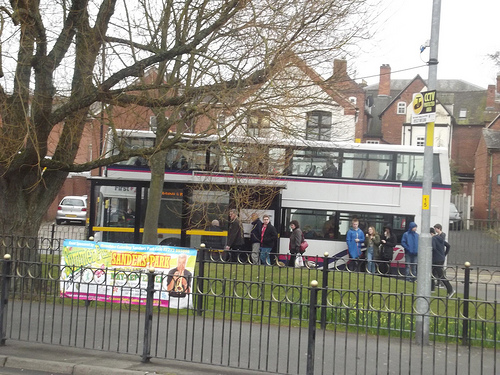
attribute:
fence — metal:
[5, 248, 495, 372]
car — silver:
[56, 193, 88, 223]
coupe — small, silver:
[28, 175, 107, 239]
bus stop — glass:
[89, 175, 283, 267]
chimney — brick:
[375, 61, 393, 97]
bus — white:
[93, 127, 451, 274]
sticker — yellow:
[421, 192, 429, 211]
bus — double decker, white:
[82, 116, 452, 286]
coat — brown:
[284, 225, 308, 255]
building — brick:
[12, 42, 493, 251]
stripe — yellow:
[88, 224, 231, 242]